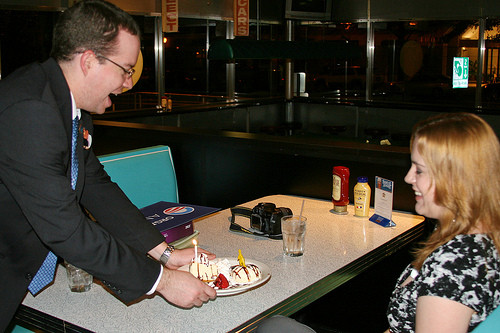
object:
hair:
[412, 112, 500, 271]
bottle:
[354, 176, 372, 217]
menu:
[369, 176, 396, 228]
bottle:
[329, 166, 350, 216]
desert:
[180, 251, 254, 287]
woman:
[389, 112, 500, 333]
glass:
[281, 215, 308, 257]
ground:
[183, 148, 317, 191]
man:
[0, 0, 216, 333]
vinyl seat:
[97, 144, 182, 201]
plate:
[177, 257, 272, 296]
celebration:
[1, 0, 500, 333]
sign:
[452, 57, 469, 88]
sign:
[235, 0, 250, 36]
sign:
[162, 2, 178, 33]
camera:
[229, 202, 293, 239]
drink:
[281, 215, 308, 258]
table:
[18, 194, 428, 333]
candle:
[231, 245, 246, 269]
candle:
[192, 238, 197, 261]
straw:
[299, 200, 304, 220]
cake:
[178, 256, 270, 296]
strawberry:
[214, 273, 229, 288]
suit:
[0, 57, 166, 332]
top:
[387, 232, 500, 332]